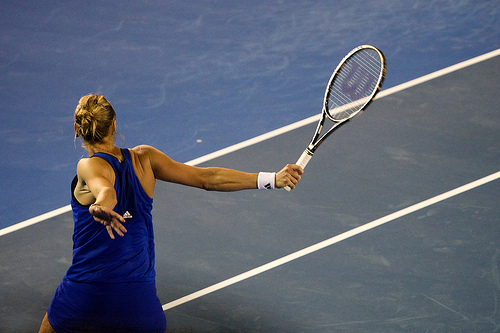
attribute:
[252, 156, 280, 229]
wrist guard — white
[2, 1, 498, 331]
ground — blue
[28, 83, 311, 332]
woman — blonde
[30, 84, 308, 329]
player — looking right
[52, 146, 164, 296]
shirt — sleeveless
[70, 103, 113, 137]
hair — tied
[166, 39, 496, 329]
lines — white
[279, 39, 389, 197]
racket — white, tennis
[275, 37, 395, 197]
tennis racket — black, white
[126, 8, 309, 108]
tennis court — blue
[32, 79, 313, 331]
person — playing tennis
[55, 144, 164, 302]
top — blue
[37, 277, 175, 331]
shorts — blue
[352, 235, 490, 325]
ground — gray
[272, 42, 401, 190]
racket — white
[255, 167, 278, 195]
wristband — white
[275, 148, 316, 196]
handle — white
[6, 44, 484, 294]
lines — white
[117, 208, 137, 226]
logo — white